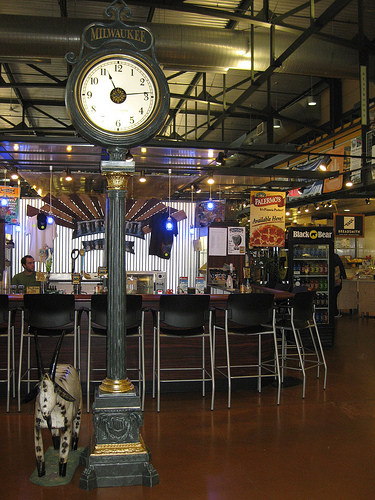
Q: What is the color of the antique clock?
A: The antique clock is black and gold.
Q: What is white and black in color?
A: The goat on the floor.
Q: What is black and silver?
A: The stools by the bar.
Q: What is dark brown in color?
A: The tiled foor.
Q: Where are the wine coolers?
A: The wine coolers are in the cooler.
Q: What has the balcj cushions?
A: The metal bar stools.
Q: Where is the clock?
A: In the room.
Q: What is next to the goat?
A: A clock.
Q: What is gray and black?
A: The goat.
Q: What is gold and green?
A: Lamp post.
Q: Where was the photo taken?
A: In a bar.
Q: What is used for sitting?
A: The chairs.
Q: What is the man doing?
A: Looking to his left.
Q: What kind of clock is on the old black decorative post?
A: Milwaukee.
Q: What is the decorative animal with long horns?
A: A goat.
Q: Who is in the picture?
A: A man.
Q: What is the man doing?
A: Tending the bar.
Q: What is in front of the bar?
A: A row of chairs.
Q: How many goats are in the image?
A: One.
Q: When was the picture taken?
A: 11.15.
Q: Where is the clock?
A: On a pole.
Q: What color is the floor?
A: Brown.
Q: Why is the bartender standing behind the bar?
A: Waiting for customers.